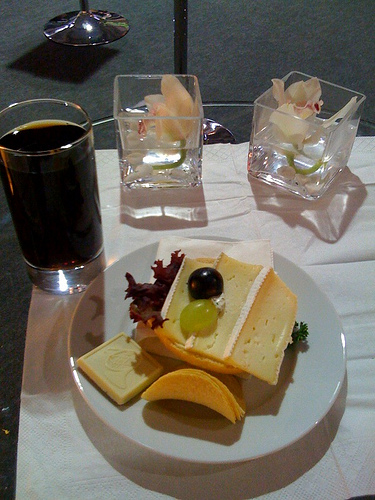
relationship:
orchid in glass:
[269, 76, 356, 175] [240, 65, 370, 203]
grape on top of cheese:
[181, 299, 218, 333] [168, 257, 296, 393]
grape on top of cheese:
[189, 264, 229, 296] [168, 257, 296, 393]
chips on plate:
[145, 364, 248, 423] [61, 237, 349, 434]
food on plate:
[75, 248, 310, 425] [65, 234, 347, 463]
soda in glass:
[5, 117, 106, 264] [1, 95, 103, 294]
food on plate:
[65, 248, 319, 440] [65, 234, 347, 463]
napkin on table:
[15, 136, 374, 499] [0, 0, 373, 499]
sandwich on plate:
[128, 239, 341, 389] [65, 234, 347, 463]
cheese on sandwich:
[157, 252, 298, 385] [128, 239, 341, 389]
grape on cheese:
[181, 299, 218, 333] [157, 252, 298, 385]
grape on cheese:
[189, 264, 229, 296] [157, 252, 298, 385]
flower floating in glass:
[121, 76, 196, 183] [114, 73, 210, 205]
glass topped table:
[248, 59, 372, 198] [236, 194, 371, 262]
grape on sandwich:
[189, 264, 229, 296] [121, 245, 303, 389]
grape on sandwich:
[181, 299, 218, 333] [81, 243, 313, 410]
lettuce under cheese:
[124, 247, 182, 330] [157, 252, 298, 385]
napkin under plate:
[15, 136, 374, 499] [65, 234, 347, 463]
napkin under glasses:
[15, 136, 374, 499] [0, 96, 106, 294]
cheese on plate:
[76, 332, 164, 407] [70, 289, 129, 342]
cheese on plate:
[53, 306, 289, 435] [258, 392, 305, 440]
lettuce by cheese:
[117, 245, 183, 336] [241, 270, 297, 387]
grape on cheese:
[189, 264, 229, 296] [136, 251, 298, 382]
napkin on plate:
[169, 227, 282, 267] [107, 245, 306, 478]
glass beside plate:
[1, 95, 103, 294] [65, 234, 347, 463]